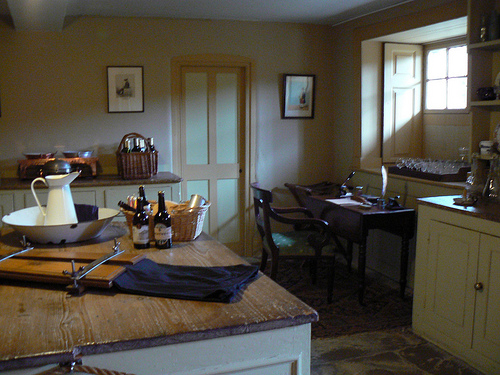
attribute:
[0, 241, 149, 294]
cutting board — wooden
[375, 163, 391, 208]
quill — feather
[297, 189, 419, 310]
desk — old, dark brown, brown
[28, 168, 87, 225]
water pitcher — white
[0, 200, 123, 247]
basin — white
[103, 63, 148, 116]
photograph — framed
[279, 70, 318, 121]
frame — black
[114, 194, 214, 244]
basket — light brown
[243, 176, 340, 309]
chair — brown, dark brown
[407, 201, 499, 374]
cabinet — white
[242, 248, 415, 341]
rug — floral design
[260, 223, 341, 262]
cushion — green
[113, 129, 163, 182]
basket — dark brown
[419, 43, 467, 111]
window — small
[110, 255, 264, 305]
table cloth — black